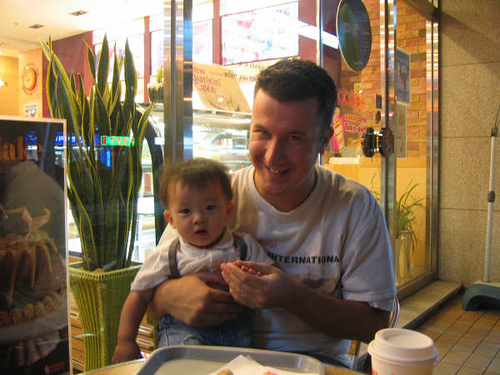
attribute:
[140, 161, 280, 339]
boy — looking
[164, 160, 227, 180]
hair — dark, short, brown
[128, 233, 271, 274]
shirt — white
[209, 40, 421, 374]
man — smiling, looking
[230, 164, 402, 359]
shirt — white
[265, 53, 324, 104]
hair — dark, short, brown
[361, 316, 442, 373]
coffe cup — white, disposable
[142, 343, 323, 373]
tray — gray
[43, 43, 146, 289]
plant — green, large, potted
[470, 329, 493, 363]
tiles — brown, square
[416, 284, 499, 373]
ground — tiled, brick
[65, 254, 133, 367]
vase — green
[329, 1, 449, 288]
door — glass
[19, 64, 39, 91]
clock — hanging